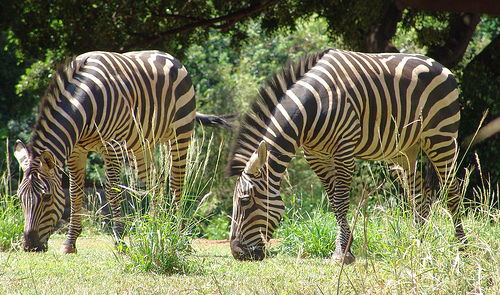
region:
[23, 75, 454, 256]
Two zebras grazing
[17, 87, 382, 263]
Two zebras with mouth in the grass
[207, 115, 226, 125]
The tail of a zebra raised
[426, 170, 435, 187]
Zebra tail hanging down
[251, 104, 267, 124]
The big mane of zebra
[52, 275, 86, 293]
Short grass on the ground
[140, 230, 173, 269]
Long grass sticking out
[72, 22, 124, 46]
Leaves of tree behind zebra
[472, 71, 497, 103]
Shadow on the leaves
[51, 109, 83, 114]
Black and white stripes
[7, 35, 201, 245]
black and white striped zebra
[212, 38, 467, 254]
black and white striped zebra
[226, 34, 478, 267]
black and white zebra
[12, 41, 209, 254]
black and white zebra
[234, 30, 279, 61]
green leaves in brown tree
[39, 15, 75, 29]
green leaves in brown tree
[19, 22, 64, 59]
green leaves in brown tree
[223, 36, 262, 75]
green leaves in brown tree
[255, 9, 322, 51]
green leaves in brown tree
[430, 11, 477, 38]
green leaves in brown tree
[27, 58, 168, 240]
WHITE AND BLACK ZEBRA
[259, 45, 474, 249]
WHITE AND BLACK ZEBRA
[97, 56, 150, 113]
WHITE AND BLACK STRIPES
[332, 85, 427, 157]
WHITE AND BLACK STRIPES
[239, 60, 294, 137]
THICK MANE ON ZEBRA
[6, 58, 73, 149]
THICK MANE ON ZEBRA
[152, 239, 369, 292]
GRASS GROWING ON GROUND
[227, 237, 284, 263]
BLACK NOSE OF ZEBRA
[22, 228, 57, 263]
BLACK NOSE OF ZEBRA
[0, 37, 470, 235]
TREES GROWING BEHIND ZEBRAS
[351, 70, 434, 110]
pattern on side of zebra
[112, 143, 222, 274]
bunch of tall green grass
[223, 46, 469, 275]
zebra grazing in green grass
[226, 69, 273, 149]
long black and white hair on back of zebra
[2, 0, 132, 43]
trees covered in green leaves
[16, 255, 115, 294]
ground covered in thick green grass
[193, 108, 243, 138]
black hair on zebra tail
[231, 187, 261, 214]
eye on head of zebra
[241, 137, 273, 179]
long black and white zebra ear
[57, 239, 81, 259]
beige hoof on leg of zebra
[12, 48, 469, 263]
two zebras grazing in a field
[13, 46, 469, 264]
two zebras eating grass on the ground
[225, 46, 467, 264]
a zebra eating grass beside another zebra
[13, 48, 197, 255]
a black and white stripped zebra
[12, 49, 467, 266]
two black and white stripped zebras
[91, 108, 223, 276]
green weeds on the ground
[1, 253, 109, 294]
green and tan grass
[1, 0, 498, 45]
green leaves on the branches of trees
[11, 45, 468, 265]
zebras in a national park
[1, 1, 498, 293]
zebras in a field at a wildlife park